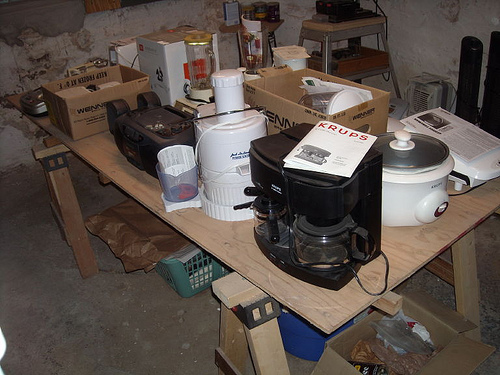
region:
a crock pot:
[379, 130, 459, 232]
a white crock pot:
[380, 124, 454, 229]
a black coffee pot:
[248, 111, 389, 288]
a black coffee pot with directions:
[252, 117, 389, 290]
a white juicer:
[146, 68, 258, 220]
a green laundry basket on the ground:
[158, 239, 226, 298]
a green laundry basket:
[158, 233, 232, 295]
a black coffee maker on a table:
[250, 120, 386, 287]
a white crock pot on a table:
[378, 116, 453, 240]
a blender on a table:
[175, 27, 222, 117]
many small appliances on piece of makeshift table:
[27, 16, 499, 341]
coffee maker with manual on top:
[238, 112, 395, 307]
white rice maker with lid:
[367, 121, 459, 228]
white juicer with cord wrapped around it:
[191, 64, 282, 226]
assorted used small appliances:
[97, 57, 495, 298]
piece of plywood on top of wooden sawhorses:
[9, 50, 494, 374]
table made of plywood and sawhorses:
[17, 37, 492, 374]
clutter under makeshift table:
[89, 205, 499, 374]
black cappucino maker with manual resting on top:
[240, 112, 397, 309]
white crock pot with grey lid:
[362, 126, 462, 238]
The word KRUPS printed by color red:
[319, 118, 374, 143]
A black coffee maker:
[246, 150, 378, 289]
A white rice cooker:
[380, 127, 452, 232]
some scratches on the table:
[258, 262, 344, 337]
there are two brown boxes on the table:
[39, 36, 410, 231]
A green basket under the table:
[153, 249, 223, 307]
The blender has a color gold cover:
[177, 27, 220, 114]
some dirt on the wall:
[8, 23, 98, 71]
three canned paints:
[239, 0, 293, 26]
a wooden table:
[6, 49, 498, 308]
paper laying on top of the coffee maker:
[240, 113, 401, 297]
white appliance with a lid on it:
[371, 122, 463, 230]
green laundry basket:
[150, 245, 231, 311]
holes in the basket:
[177, 254, 216, 293]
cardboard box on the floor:
[303, 298, 498, 373]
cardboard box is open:
[299, 295, 497, 373]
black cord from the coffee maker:
[350, 248, 401, 303]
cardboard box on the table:
[236, 55, 406, 157]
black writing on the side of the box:
[251, 98, 308, 138]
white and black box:
[129, 26, 236, 116]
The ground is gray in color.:
[30, 310, 121, 363]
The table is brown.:
[207, 222, 239, 250]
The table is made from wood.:
[216, 225, 250, 250]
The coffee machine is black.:
[246, 130, 391, 296]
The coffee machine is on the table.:
[249, 109, 384, 293]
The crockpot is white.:
[376, 125, 461, 230]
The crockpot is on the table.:
[376, 127, 460, 230]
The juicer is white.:
[187, 69, 272, 226]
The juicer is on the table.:
[192, 66, 267, 224]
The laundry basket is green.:
[158, 250, 227, 295]